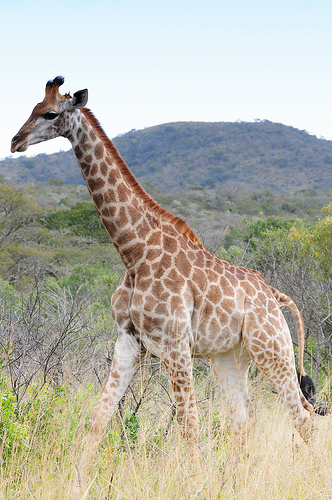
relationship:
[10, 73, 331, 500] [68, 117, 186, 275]
giraffe has neck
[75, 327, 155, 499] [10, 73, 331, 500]
leg on giraffe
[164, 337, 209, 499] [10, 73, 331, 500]
leg on giraffe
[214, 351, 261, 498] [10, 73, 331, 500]
leg on giraffe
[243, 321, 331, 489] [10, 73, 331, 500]
leg on giraffe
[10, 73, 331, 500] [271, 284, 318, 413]
giraffe has tail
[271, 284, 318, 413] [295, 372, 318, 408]
tail has hair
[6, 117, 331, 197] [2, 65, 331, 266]
hill in background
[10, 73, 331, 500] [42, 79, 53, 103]
giraffe has horn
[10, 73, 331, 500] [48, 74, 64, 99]
giraffe has horn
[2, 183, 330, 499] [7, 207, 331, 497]
greenery on ground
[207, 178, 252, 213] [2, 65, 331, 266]
tree in background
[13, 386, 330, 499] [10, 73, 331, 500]
grass under giraffe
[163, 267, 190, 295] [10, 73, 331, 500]
spot on giraffe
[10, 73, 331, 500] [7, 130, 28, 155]
giraffe has snout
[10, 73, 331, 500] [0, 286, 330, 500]
giraffe in meadow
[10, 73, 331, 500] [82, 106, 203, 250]
giraffe has mane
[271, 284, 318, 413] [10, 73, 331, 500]
tail on giraffe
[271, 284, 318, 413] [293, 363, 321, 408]
tail has tuft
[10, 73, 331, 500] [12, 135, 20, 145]
giraffe has nostril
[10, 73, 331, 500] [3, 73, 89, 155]
giraffe has head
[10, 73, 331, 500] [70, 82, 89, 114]
giraffe has ear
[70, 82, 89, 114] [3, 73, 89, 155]
ear on head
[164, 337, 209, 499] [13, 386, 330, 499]
leg in grass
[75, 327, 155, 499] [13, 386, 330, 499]
leg in grass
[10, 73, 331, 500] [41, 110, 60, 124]
giraffe has eye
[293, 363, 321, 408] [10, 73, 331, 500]
tuft on giraffe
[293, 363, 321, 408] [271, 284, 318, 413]
tuft on tail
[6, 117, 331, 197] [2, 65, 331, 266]
mountain in background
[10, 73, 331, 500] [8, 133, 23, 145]
giraffe has nose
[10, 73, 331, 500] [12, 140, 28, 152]
giraffe has mouth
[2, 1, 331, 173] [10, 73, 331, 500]
sky behind giraffe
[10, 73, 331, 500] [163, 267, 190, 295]
giraffe has spot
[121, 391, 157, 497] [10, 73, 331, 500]
branch in front of giraffe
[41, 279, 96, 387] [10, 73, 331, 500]
branch in front of giraffe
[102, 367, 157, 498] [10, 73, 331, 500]
branch in front of giraffe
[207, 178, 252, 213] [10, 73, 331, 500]
tree behind giraffe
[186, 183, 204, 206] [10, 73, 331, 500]
tree behind giraffe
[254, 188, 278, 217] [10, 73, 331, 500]
tree behind giraffe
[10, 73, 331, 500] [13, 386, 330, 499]
giraffe in grass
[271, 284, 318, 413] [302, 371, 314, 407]
tail has tip